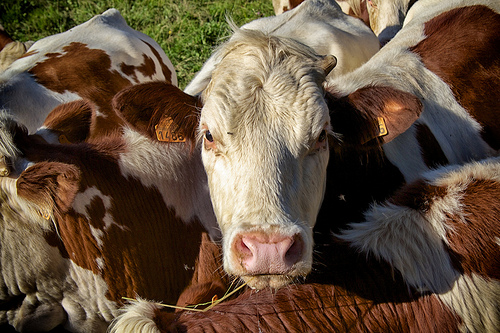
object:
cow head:
[106, 30, 423, 295]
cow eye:
[309, 119, 329, 150]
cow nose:
[229, 227, 306, 272]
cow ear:
[109, 79, 199, 146]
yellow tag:
[149, 111, 189, 145]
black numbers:
[159, 131, 164, 141]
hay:
[120, 277, 253, 314]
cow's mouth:
[221, 267, 306, 287]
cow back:
[5, 18, 140, 90]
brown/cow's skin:
[68, 55, 99, 85]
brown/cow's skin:
[142, 226, 172, 276]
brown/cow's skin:
[472, 22, 500, 116]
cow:
[0, 6, 180, 133]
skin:
[21, 38, 130, 126]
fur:
[196, 28, 330, 234]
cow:
[110, 0, 500, 291]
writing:
[157, 128, 184, 142]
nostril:
[230, 233, 254, 259]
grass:
[1, 0, 273, 88]